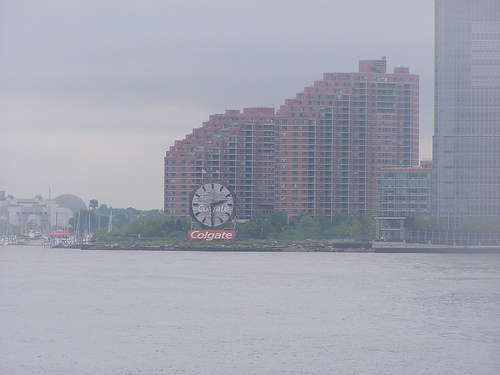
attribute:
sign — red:
[184, 231, 233, 242]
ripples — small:
[275, 342, 304, 353]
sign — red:
[181, 229, 241, 245]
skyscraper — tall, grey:
[432, 5, 499, 237]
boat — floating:
[3, 234, 29, 249]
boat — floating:
[16, 225, 46, 242]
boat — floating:
[41, 231, 76, 248]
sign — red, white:
[188, 228, 235, 240]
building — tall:
[376, 1, 498, 245]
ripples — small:
[0, 246, 217, 372]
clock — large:
[188, 177, 241, 229]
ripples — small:
[169, 320, 287, 372]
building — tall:
[434, 0, 498, 244]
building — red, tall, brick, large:
[157, 53, 422, 230]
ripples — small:
[308, 326, 353, 361]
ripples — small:
[274, 277, 366, 318]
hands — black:
[207, 195, 231, 228]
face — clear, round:
[191, 178, 234, 232]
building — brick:
[162, 53, 420, 253]